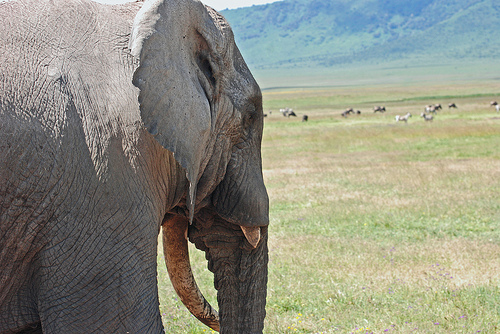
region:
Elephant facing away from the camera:
[2, 0, 271, 331]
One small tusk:
[238, 218, 265, 250]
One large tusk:
[159, 200, 224, 331]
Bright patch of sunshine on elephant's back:
[3, 2, 158, 162]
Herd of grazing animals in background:
[263, 99, 499, 131]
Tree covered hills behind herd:
[220, 0, 497, 67]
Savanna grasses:
[156, 73, 493, 333]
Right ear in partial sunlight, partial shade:
[131, 0, 232, 227]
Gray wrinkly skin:
[45, 204, 134, 329]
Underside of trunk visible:
[191, 215, 272, 332]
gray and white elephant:
[8, 0, 296, 332]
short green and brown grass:
[295, 173, 370, 220]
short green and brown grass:
[411, 115, 471, 195]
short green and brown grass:
[314, 219, 362, 264]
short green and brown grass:
[308, 232, 378, 294]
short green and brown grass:
[397, 138, 465, 238]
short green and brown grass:
[330, 256, 384, 296]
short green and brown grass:
[320, 189, 431, 229]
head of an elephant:
[140, 11, 287, 240]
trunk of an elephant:
[215, 210, 275, 250]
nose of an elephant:
[183, 180, 300, 332]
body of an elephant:
[18, 22, 116, 164]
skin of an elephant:
[16, 40, 127, 145]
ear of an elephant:
[135, 4, 237, 204]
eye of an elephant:
[230, 96, 261, 124]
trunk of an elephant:
[160, 190, 227, 327]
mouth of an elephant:
[172, 193, 227, 248]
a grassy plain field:
[326, 141, 476, 270]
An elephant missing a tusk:
[2, 0, 270, 330]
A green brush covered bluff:
[220, 0, 498, 73]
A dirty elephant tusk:
[157, 210, 219, 330]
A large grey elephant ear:
[134, 0, 226, 223]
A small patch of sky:
[199, 0, 278, 11]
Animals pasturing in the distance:
[262, 102, 498, 124]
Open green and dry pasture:
[157, 75, 499, 326]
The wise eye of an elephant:
[246, 110, 254, 122]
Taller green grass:
[364, 88, 499, 103]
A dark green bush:
[330, 10, 374, 30]